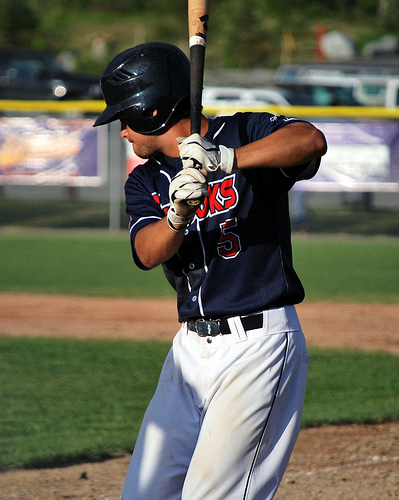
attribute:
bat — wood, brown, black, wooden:
[179, 0, 213, 211]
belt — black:
[168, 312, 302, 340]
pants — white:
[120, 298, 313, 499]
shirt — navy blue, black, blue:
[104, 108, 340, 311]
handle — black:
[183, 46, 210, 178]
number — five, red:
[213, 212, 253, 261]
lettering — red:
[145, 176, 268, 273]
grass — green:
[0, 222, 397, 468]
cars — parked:
[1, 45, 396, 111]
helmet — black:
[74, 34, 221, 131]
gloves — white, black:
[163, 132, 239, 233]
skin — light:
[98, 97, 338, 274]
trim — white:
[125, 153, 317, 316]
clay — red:
[2, 294, 397, 346]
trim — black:
[243, 332, 300, 498]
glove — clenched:
[166, 171, 215, 230]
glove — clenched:
[174, 135, 246, 174]